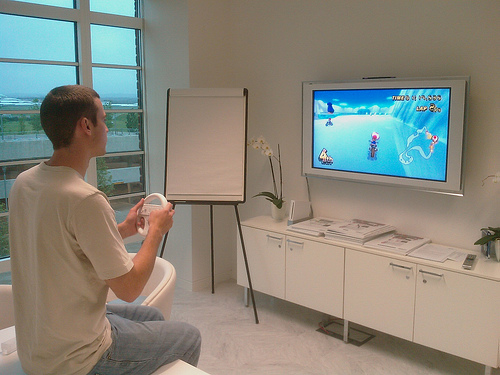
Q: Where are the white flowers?
A: On top of the cabinet.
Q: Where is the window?
A: Next to the boy.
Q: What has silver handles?
A: The cabinets.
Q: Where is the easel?
A: Next to the window.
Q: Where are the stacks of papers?
A: On the cabinet.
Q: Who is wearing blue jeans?
A: The boy.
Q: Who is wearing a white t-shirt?
A: The boy.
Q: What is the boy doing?
A: Playing a video game.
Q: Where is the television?
A: On the wall.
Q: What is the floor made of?
A: Carpet.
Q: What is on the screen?
A: A video game.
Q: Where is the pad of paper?
A: The left of the tv.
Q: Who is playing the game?
A: The young man.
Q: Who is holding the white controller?
A: The the young man.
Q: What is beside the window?
A: An art easel.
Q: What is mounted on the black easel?
A: White plain paper.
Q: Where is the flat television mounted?
A: On a white painted wall.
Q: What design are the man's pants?
A: Blue jeans.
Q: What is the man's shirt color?
A: Beige.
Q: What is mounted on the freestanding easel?
A: Large, white paper pad.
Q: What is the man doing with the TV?
A: Playing a game.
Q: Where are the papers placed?
A: On a white shelf.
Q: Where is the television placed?
A: In a room.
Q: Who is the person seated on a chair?
A: A young man.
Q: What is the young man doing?
A: Playing a video game.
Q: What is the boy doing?
A: Playing Wii.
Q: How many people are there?
A: One.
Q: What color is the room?
A: White.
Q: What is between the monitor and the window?
A: Easel.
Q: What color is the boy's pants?
A: Denim blue.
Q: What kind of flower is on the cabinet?
A: Orchid.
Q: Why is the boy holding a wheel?
A: To manipulate the game.